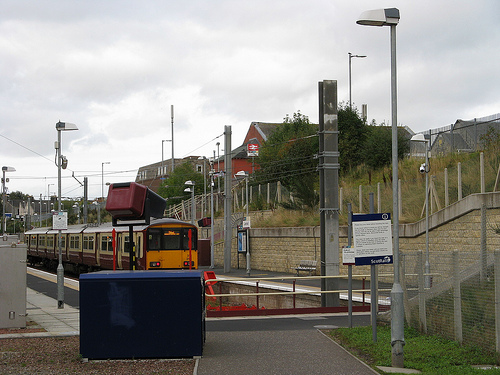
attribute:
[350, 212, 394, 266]
sign — black, white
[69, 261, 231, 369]
bin — in front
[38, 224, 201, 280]
train — passenger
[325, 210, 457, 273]
sign — blue, white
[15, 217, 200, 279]
train — driving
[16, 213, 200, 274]
train — yellow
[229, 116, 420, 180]
building — on right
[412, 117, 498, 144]
building — on right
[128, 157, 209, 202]
building — on right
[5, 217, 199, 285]
train — orange, black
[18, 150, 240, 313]
train — ornage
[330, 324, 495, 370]
grass — short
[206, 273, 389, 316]
railing — white, red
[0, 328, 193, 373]
rocks — brown